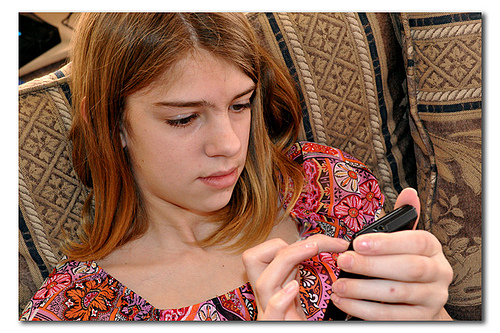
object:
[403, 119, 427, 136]
ground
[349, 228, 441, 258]
finger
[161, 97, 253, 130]
eyes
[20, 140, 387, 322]
dress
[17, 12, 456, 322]
girl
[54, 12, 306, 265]
brown hair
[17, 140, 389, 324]
orange shirt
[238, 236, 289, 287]
finger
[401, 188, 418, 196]
thumb nail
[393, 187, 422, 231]
thumb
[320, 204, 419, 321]
object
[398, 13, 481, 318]
pillow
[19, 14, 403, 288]
pillow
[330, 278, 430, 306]
ring finger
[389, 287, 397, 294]
ouchy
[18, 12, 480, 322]
couch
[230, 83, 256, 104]
eyebrow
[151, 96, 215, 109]
eyebrow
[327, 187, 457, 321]
hand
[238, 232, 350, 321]
hand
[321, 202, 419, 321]
cellphone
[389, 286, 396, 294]
mark